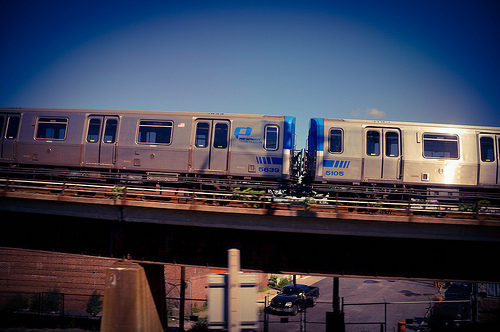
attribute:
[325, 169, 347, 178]
number 5105 — blue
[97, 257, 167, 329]
support — concrete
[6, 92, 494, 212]
train — silver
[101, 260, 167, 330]
support — concrete, bridge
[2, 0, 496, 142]
sky — blue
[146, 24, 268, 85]
cloud — small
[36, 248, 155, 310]
wall — brick